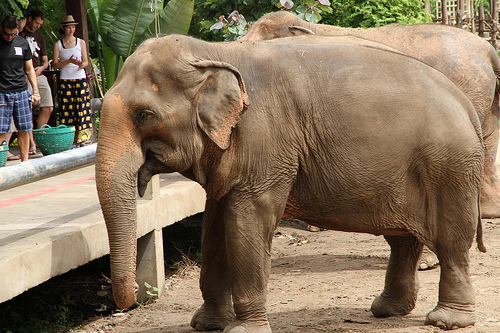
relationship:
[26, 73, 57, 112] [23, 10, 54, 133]
shorts on man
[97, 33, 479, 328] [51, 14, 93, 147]
elephant near girl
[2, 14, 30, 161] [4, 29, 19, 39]
man wearing specks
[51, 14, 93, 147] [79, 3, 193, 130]
girl near plant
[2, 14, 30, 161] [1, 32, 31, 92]
man wearing t-shirt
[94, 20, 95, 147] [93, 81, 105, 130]
girl wearing skirt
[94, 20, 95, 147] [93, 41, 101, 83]
girl wearing t-shirt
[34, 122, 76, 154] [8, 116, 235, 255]
basket on floor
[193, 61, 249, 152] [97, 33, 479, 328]
ear of elephant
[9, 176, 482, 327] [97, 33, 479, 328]
floor in front of elephant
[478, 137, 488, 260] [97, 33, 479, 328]
tail of elephant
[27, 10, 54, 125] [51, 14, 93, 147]
man standing next to girl